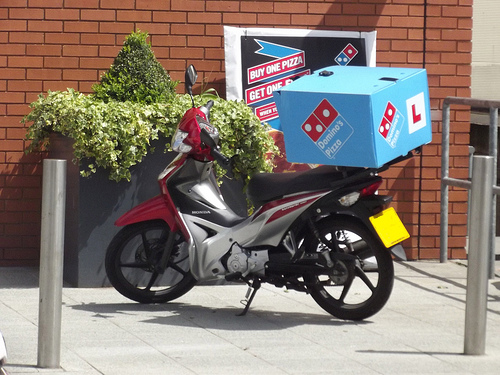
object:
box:
[270, 65, 432, 170]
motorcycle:
[104, 63, 413, 322]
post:
[36, 157, 66, 366]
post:
[459, 153, 497, 355]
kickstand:
[231, 282, 259, 317]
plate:
[366, 205, 408, 251]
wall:
[0, 0, 474, 267]